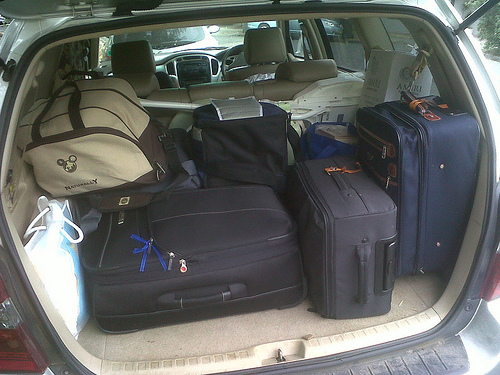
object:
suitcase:
[284, 155, 401, 321]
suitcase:
[169, 94, 297, 197]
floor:
[475, 318, 497, 362]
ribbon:
[130, 225, 168, 276]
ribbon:
[325, 157, 359, 177]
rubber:
[286, 324, 471, 375]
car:
[0, 0, 500, 375]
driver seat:
[104, 38, 190, 104]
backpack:
[12, 69, 188, 215]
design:
[56, 149, 76, 175]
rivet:
[438, 162, 443, 171]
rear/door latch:
[274, 343, 288, 365]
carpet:
[143, 328, 243, 346]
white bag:
[23, 195, 91, 341]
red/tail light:
[0, 285, 52, 375]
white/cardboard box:
[357, 47, 435, 108]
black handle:
[324, 165, 349, 191]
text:
[55, 175, 100, 192]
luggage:
[17, 69, 482, 336]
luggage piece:
[81, 180, 313, 331]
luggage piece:
[295, 147, 401, 319]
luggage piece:
[351, 90, 483, 278]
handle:
[156, 282, 253, 312]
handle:
[355, 240, 375, 311]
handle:
[397, 85, 431, 116]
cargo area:
[1, 0, 488, 375]